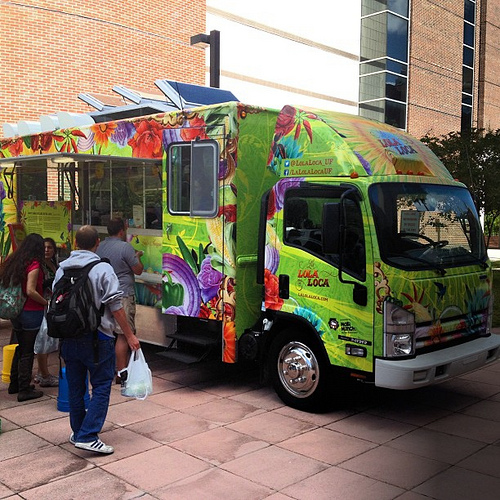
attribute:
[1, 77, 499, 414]
food truck — brightly colored, green, colorful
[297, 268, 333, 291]
lola loca — pictured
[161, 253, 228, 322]
picture — purple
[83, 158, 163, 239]
window — for ordering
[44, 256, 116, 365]
backpack — black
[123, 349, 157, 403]
bag — made of plastic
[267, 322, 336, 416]
wheel — shiny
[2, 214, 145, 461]
people — waiting for food, waiting for service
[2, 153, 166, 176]
awning — for protection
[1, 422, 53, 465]
square — beige colored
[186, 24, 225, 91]
light post — black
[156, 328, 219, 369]
steps — black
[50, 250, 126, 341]
hoody — grey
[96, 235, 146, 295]
shirt — grey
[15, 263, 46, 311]
shirt — pink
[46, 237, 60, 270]
hair — black